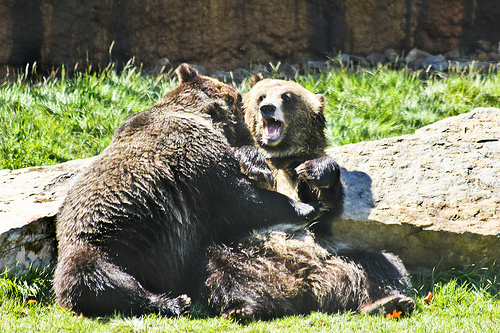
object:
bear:
[189, 222, 414, 319]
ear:
[248, 70, 263, 91]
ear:
[173, 62, 199, 82]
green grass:
[0, 71, 499, 169]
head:
[240, 73, 324, 160]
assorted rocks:
[404, 48, 433, 62]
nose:
[260, 104, 276, 114]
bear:
[55, 62, 331, 315]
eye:
[283, 92, 293, 101]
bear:
[236, 75, 344, 236]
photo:
[0, 0, 499, 333]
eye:
[259, 95, 265, 101]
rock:
[0, 106, 499, 276]